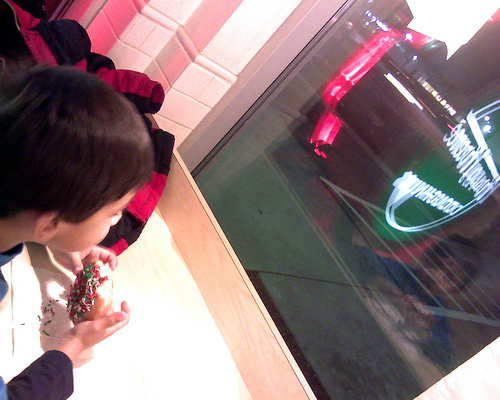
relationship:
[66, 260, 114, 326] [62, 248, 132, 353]
donut in child hand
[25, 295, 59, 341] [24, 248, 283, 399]
sprinkles falling onto table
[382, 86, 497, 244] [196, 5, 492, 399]
logo in window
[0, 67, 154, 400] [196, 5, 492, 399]
boy looking out window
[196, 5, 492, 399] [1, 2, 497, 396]
window at doughnut shop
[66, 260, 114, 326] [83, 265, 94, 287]
donut with sprinkles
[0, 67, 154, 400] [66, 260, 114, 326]
boy holding donut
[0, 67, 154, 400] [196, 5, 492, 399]
boy in window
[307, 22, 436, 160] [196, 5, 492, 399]
red light in window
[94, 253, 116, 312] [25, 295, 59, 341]
donut with sprinkles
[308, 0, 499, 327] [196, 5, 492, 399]
reflection in a plate glass window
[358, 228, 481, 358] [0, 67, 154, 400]
reflection of a boy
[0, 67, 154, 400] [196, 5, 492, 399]
boy sitting in front of window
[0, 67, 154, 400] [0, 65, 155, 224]
boy with black hair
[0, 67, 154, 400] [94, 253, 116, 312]
boy eating a donut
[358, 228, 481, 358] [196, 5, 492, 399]
reflection in window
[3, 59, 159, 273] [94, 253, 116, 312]
boy holding donut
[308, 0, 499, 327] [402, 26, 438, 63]
reflection on store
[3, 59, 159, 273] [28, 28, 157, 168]
boy has coat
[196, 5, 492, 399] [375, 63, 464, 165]
window in a restaurant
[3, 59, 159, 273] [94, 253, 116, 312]
boy eating a donut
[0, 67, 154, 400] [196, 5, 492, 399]
boy looking out of window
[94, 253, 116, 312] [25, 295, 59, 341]
donut has sprinkles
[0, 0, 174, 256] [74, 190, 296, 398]
coat on counter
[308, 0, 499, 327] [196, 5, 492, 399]
reflection in window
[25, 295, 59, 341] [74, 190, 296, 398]
sprinkles on counter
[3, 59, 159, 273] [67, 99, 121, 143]
boy has black hair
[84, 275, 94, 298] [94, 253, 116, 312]
sprinkle on donut